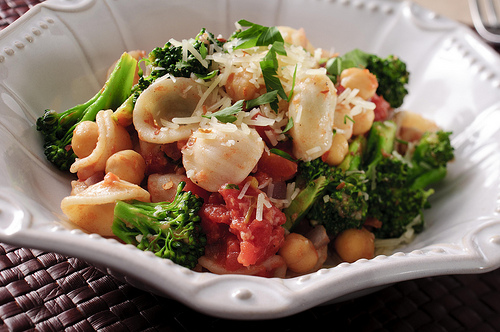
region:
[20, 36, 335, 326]
plat is white in color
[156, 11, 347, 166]
food has white rice topings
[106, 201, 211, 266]
brocoli are gren in color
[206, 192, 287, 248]
the red part is apetisimg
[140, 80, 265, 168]
the food contains white fruits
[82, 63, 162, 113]
brocoli stalks are light green in color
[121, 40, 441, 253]
the food is delicious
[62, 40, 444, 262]
a beautiful looking food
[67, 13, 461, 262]
a delicious looking food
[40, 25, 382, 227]
a sweet looking food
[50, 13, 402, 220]
a tasty looking food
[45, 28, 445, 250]
a cool looking food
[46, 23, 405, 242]
a hot looking food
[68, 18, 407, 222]
a beautiful delicious looking food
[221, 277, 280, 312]
a part of the plate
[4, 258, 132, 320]
a part of the table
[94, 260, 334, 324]
a design on the table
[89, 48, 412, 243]
this is the food on the plate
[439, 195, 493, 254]
this is the plate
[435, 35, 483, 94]
the plate is white in color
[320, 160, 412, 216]
these are the broccoli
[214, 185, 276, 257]
these are the tomato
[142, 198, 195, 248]
the broccoli is green in color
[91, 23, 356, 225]
the food is spicy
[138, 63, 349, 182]
orange lobster in bowl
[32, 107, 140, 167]
orange legumes in bowl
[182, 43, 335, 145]
white cheese on salad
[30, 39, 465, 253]
green broccoli in salad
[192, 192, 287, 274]
red tomatoes in salad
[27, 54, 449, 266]
salad in white bowl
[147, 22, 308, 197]
cheese is white and shredded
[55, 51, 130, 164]
pieces of cooked broccoli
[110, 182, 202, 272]
broccoli is dark green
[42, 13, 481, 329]
bowl on dark brown table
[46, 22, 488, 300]
food in a bowl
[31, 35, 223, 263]
cut up pieces of broccoli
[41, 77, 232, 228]
pieces of small shell pasta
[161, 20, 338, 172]
white flakes of shredded cheese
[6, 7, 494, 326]
a fancy white bowl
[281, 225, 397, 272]
chick peas in the mixture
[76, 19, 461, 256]
a pasta and veggie mixture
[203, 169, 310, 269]
a red sauce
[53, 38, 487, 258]
broccoli and chick peas together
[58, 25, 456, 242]
a broccoli and pasta mixture